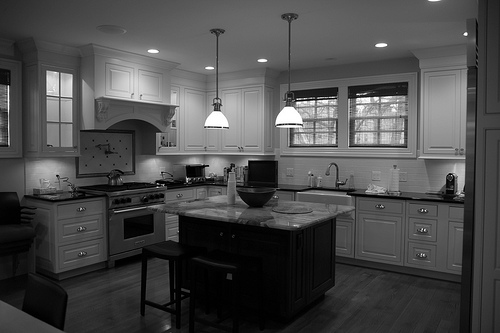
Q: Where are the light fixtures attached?
A: The ceiling.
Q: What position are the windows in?
A: Closed.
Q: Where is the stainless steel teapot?
A: On stovetop.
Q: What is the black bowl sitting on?
A: A kitchen island.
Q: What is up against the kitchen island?
A: Two black stools.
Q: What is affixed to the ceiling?
A: Two hanging lights.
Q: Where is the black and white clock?
A: Over the stove.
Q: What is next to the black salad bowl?
A: A white bottle.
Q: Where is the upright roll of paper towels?
A: Next to the sink.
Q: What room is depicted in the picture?
A: A kitchen.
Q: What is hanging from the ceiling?
A: Lights.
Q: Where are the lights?
A: Hanging from the ceiling.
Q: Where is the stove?
A: To the far left.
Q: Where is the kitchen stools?
A: Near the kitchen island.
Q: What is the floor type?
A: Wood.